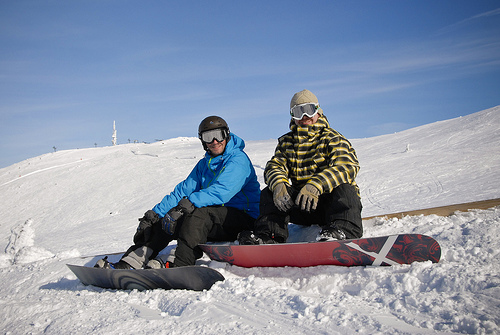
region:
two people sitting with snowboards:
[47, 82, 454, 299]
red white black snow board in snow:
[190, 231, 450, 282]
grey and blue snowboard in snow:
[49, 253, 232, 309]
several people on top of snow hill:
[51, 129, 168, 158]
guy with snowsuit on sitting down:
[235, 86, 374, 237]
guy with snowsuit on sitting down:
[90, 109, 275, 268]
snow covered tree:
[105, 115, 121, 149]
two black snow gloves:
[124, 193, 200, 244]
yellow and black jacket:
[267, 118, 370, 193]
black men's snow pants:
[144, 198, 256, 261]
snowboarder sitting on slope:
[166, 94, 251, 254]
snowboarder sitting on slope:
[259, 62, 377, 237]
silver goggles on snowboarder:
[200, 127, 235, 144]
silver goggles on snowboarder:
[293, 100, 319, 115]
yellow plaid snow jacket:
[280, 134, 358, 189]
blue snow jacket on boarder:
[173, 129, 285, 216]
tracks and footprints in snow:
[237, 248, 417, 325]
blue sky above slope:
[59, 31, 424, 116]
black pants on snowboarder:
[120, 207, 219, 252]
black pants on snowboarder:
[267, 186, 354, 226]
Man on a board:
[197, 230, 444, 269]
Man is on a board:
[195, 234, 447, 266]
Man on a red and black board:
[195, 231, 442, 269]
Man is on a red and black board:
[194, 232, 446, 269]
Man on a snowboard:
[62, 256, 225, 295]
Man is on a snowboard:
[63, 257, 225, 294]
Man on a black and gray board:
[60, 256, 225, 295]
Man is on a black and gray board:
[62, 255, 228, 296]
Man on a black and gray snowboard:
[63, 259, 226, 293]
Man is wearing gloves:
[134, 197, 200, 238]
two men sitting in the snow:
[102, 79, 394, 331]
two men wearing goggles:
[167, 81, 326, 170]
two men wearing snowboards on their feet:
[108, 111, 368, 326]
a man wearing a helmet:
[178, 108, 234, 175]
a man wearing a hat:
[288, 89, 331, 136]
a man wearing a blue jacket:
[162, 115, 246, 237]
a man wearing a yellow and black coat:
[270, 82, 352, 207]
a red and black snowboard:
[255, 227, 437, 278]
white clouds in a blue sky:
[272, 14, 467, 101]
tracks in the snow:
[218, 277, 470, 333]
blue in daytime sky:
[0, 2, 497, 164]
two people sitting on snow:
[65, 87, 442, 290]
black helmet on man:
[199, 113, 229, 151]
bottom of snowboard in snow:
[204, 233, 441, 268]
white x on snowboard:
[345, 235, 402, 268]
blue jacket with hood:
[156, 133, 260, 215]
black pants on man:
[133, 205, 250, 266]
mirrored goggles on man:
[290, 101, 319, 120]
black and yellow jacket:
[266, 126, 359, 189]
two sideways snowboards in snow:
[66, 231, 441, 286]